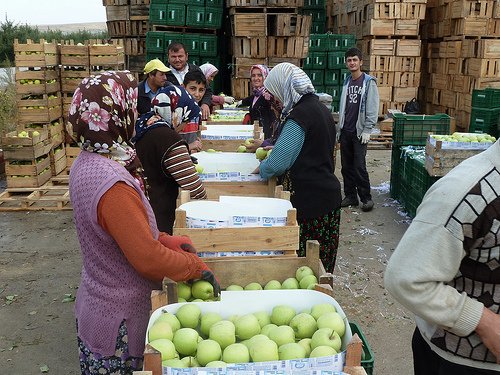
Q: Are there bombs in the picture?
A: No, there are no bombs.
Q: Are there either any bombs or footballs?
A: No, there are no bombs or footballs.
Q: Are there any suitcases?
A: No, there are no suitcases.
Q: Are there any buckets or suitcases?
A: No, there are no suitcases or buckets.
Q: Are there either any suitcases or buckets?
A: No, there are no suitcases or buckets.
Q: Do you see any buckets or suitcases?
A: No, there are no suitcases or buckets.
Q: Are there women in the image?
A: Yes, there is a woman.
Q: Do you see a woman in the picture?
A: Yes, there is a woman.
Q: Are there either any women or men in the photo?
A: Yes, there is a woman.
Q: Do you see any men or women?
A: Yes, there is a woman.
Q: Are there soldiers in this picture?
A: No, there are no soldiers.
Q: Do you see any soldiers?
A: No, there are no soldiers.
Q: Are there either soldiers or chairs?
A: No, there are no soldiers or chairs.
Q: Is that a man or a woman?
A: That is a woman.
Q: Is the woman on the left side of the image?
A: Yes, the woman is on the left of the image.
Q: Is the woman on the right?
A: No, the woman is on the left of the image.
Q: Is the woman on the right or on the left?
A: The woman is on the left of the image.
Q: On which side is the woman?
A: The woman is on the left of the image.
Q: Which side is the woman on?
A: The woman is on the left of the image.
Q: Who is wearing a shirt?
A: The woman is wearing a shirt.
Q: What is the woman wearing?
A: The woman is wearing a shirt.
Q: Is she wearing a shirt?
A: Yes, the woman is wearing a shirt.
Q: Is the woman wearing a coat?
A: No, the woman is wearing a shirt.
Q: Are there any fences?
A: No, there are no fences.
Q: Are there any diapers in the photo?
A: No, there are no diapers.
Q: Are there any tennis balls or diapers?
A: No, there are no diapers or tennis balls.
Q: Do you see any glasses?
A: No, there are no glasses.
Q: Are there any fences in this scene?
A: No, there are no fences.